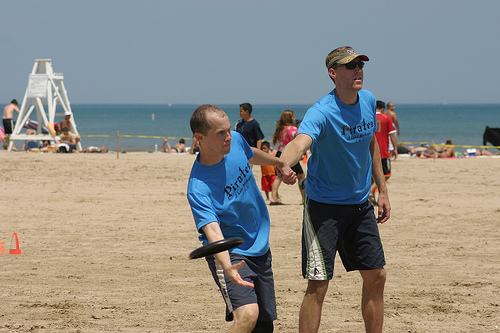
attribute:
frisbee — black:
[172, 223, 258, 273]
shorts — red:
[257, 161, 304, 215]